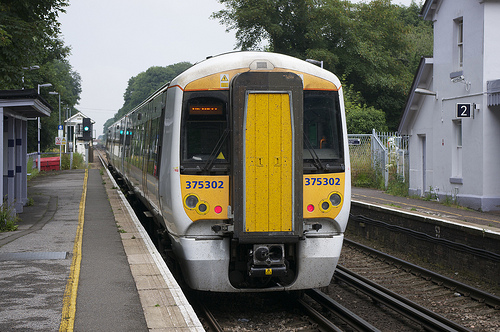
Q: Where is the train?
A: On the tracks.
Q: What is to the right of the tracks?
A: A white building.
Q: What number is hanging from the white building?
A: 2.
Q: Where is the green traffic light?
A: On the left side of the tracks.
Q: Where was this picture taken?
A: Train stop.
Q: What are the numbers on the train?
A: 375302.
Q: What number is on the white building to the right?
A: 2.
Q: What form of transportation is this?
A: Train.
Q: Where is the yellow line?
A: On platform near train.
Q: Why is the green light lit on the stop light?
A: To indicate it's ok to go.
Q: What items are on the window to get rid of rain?
A: Windshield wipers.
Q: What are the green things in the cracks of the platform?
A: Weeds.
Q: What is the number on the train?
A: 375302.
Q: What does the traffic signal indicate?
A: Green for go.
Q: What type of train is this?
A: Passenger train.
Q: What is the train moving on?
A: Railroad tracks.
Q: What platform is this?
A: 2.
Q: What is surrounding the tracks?
A: Trees.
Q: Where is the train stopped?
A: A platform.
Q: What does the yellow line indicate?
A: Where to stand safely.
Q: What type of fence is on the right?
A: A white metal fence.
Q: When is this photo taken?
A: Daytime.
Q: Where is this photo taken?
A: Train station.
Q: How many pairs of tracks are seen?
A: Two.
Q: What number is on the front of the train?
A: 375302.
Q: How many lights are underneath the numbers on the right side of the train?
A: Three.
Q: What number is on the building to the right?
A: Two.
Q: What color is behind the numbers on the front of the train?
A: Yellow.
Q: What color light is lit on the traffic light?
A: Green.